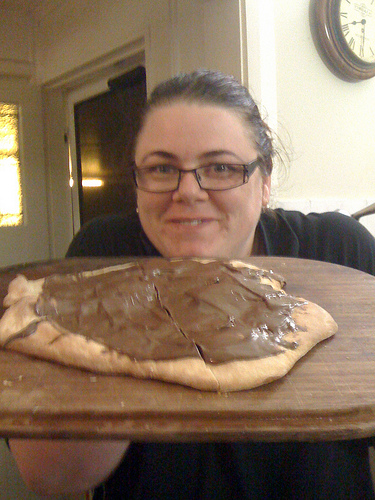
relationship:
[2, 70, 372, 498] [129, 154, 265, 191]
woman wearing glasses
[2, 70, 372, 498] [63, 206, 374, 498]
woman has shirt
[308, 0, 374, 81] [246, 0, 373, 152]
clock on wall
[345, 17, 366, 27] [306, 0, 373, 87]
hand on clock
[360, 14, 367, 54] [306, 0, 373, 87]
hand on clock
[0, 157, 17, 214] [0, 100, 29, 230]
light shining through window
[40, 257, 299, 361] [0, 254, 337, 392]
chocolate on crust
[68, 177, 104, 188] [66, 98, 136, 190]
light coming through window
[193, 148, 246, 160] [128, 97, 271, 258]
eyebrow on face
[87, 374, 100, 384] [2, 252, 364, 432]
crumb on plate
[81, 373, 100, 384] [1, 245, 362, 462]
crumb on plate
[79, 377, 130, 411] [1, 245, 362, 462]
crumb on plate